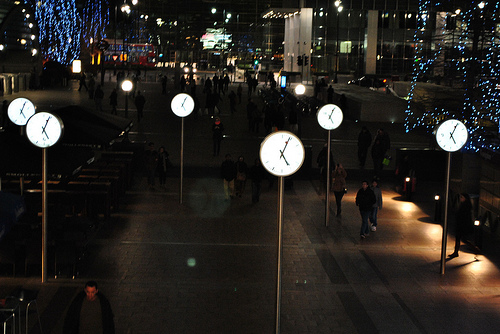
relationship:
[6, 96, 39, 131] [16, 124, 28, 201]
clocks on pole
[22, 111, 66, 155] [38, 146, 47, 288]
clocks on pole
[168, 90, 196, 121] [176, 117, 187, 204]
clocks on pole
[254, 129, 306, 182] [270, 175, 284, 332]
clocks on pole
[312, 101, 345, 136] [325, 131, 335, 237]
clocks on pole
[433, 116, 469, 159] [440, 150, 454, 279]
clocks on pole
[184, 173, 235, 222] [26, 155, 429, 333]
reflection in pathway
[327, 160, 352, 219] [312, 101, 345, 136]
people under clocks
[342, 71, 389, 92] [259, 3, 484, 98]
car front of buildings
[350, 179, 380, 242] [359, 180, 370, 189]
people with hair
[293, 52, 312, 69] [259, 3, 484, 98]
lights in front of buildings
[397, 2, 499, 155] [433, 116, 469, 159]
lights over clocks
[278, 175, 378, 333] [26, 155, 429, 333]
edge of pathway